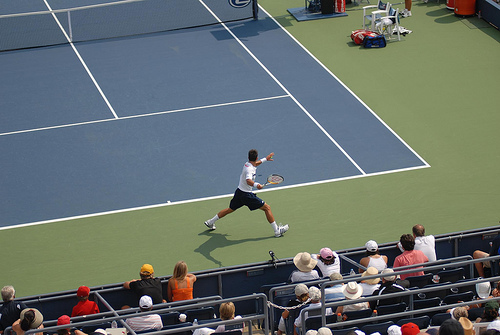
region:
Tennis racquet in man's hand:
[265, 170, 283, 190]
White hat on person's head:
[362, 240, 380, 247]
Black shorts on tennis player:
[231, 189, 266, 210]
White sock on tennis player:
[272, 223, 279, 232]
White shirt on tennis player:
[241, 158, 255, 191]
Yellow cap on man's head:
[139, 262, 155, 274]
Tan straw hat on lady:
[295, 253, 317, 271]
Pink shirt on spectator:
[393, 249, 428, 271]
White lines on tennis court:
[3, 3, 427, 224]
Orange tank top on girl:
[170, 278, 194, 297]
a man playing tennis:
[105, 62, 375, 308]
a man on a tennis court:
[19, 41, 466, 290]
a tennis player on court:
[100, 16, 397, 303]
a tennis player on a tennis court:
[115, 83, 425, 288]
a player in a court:
[119, 79, 398, 296]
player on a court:
[132, 81, 439, 303]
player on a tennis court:
[100, 146, 397, 278]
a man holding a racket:
[99, 79, 392, 276]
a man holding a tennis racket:
[166, 100, 346, 241]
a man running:
[182, 114, 327, 264]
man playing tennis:
[201, 133, 295, 240]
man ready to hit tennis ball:
[203, 142, 296, 246]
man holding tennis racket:
[208, 147, 290, 234]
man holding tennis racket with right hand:
[213, 145, 291, 237]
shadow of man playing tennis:
[190, 230, 272, 265]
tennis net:
[1, 0, 265, 42]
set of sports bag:
[345, 25, 389, 52]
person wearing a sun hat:
[288, 249, 318, 274]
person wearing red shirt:
[67, 293, 102, 316]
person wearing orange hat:
[136, 260, 156, 283]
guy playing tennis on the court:
[190, 124, 302, 243]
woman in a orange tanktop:
[164, 258, 197, 303]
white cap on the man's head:
[362, 236, 379, 252]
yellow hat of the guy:
[132, 260, 155, 277]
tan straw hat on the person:
[290, 244, 318, 275]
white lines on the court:
[100, 81, 187, 163]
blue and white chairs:
[360, 0, 405, 42]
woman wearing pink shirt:
[386, 233, 429, 278]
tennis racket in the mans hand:
[267, 168, 282, 193]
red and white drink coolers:
[442, 2, 474, 24]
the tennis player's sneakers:
[204, 213, 296, 243]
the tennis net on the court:
[3, 0, 278, 82]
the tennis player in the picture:
[213, 149, 298, 240]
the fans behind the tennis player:
[11, 254, 499, 331]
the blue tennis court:
[5, 3, 428, 229]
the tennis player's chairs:
[349, 5, 422, 49]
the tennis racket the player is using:
[266, 172, 293, 200]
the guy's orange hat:
[133, 260, 156, 274]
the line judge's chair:
[284, 1, 361, 21]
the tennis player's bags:
[347, 27, 390, 56]